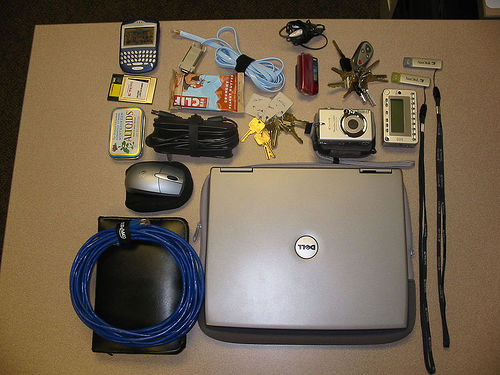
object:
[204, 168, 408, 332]
laptop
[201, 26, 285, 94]
wire-roll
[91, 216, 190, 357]
book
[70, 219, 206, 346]
wire-roll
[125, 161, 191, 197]
mouse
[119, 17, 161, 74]
phone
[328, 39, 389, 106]
keys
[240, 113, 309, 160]
keys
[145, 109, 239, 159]
wires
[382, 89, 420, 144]
gadget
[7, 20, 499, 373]
table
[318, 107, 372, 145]
camera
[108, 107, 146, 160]
altoids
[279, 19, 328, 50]
earbuds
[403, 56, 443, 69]
storage-device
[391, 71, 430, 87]
storage-device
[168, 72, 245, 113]
energy-bar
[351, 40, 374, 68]
remote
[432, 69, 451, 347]
lanyard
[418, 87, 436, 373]
lanyard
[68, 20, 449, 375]
electronics